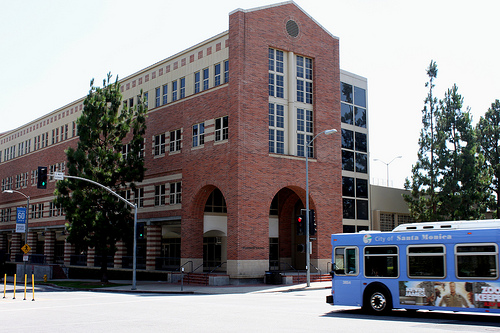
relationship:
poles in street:
[2, 261, 54, 295] [2, 291, 329, 319]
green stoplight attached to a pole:
[37, 166, 49, 190] [37, 162, 144, 291]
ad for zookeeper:
[398, 280, 498, 311] [434, 279, 498, 302]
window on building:
[295, 52, 314, 109] [6, 4, 342, 274]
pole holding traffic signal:
[130, 204, 137, 291] [36, 165, 47, 188]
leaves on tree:
[50, 71, 147, 251] [51, 70, 148, 284]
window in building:
[353, 85, 367, 106] [339, 65, 371, 252]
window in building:
[353, 106, 363, 126] [339, 65, 371, 252]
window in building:
[355, 132, 369, 151] [339, 65, 371, 252]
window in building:
[341, 152, 354, 172] [339, 65, 371, 252]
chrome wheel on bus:
[363, 281, 405, 315] [310, 211, 497, 314]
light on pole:
[324, 126, 336, 136] [304, 127, 341, 299]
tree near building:
[17, 82, 192, 272] [1, 0, 370, 281]